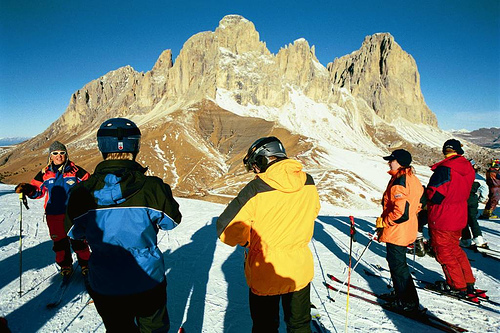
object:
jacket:
[217, 159, 322, 296]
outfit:
[417, 153, 489, 305]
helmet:
[243, 135, 291, 173]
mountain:
[0, 19, 214, 198]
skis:
[322, 273, 472, 333]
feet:
[377, 292, 428, 320]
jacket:
[63, 158, 181, 302]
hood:
[258, 159, 307, 193]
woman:
[15, 141, 91, 285]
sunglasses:
[50, 150, 66, 156]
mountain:
[267, 29, 460, 200]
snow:
[211, 82, 460, 217]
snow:
[182, 195, 221, 225]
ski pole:
[329, 227, 380, 303]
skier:
[215, 135, 320, 333]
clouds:
[0, 116, 39, 138]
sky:
[442, 4, 496, 111]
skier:
[375, 149, 428, 321]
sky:
[2, 2, 93, 81]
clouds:
[438, 105, 498, 127]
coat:
[28, 155, 91, 216]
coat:
[375, 165, 424, 247]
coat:
[426, 154, 476, 231]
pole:
[345, 215, 356, 304]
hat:
[383, 148, 412, 167]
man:
[416, 138, 488, 303]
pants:
[427, 224, 476, 291]